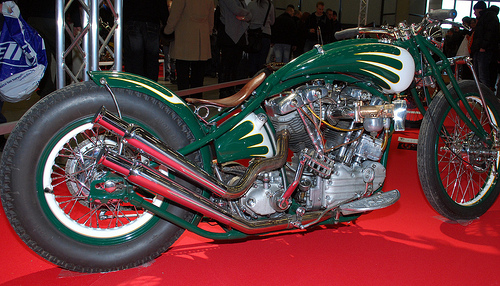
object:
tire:
[415, 80, 500, 223]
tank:
[251, 38, 416, 97]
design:
[353, 42, 417, 95]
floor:
[0, 62, 500, 286]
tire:
[1, 70, 216, 273]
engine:
[262, 84, 338, 153]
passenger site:
[186, 72, 267, 126]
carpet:
[0, 75, 500, 286]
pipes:
[91, 105, 335, 234]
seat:
[185, 72, 266, 126]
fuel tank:
[252, 38, 420, 98]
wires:
[296, 95, 322, 131]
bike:
[0, 9, 500, 274]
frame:
[94, 38, 412, 243]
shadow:
[1, 206, 500, 286]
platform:
[0, 49, 500, 286]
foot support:
[338, 188, 401, 215]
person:
[163, 0, 340, 111]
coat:
[164, 0, 213, 61]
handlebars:
[334, 9, 457, 40]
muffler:
[94, 105, 331, 235]